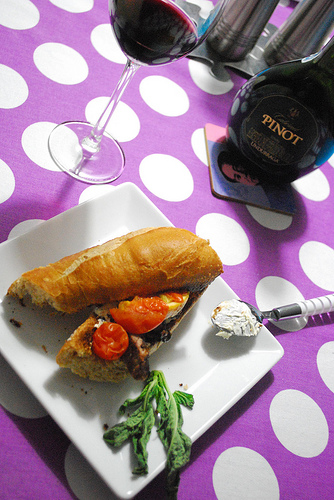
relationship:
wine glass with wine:
[46, 0, 225, 185] [108, 0, 198, 67]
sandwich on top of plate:
[8, 222, 224, 384] [1, 181, 285, 500]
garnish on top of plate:
[104, 367, 195, 476] [1, 181, 285, 500]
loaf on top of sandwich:
[8, 225, 223, 312] [8, 222, 224, 384]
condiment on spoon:
[212, 298, 261, 342] [211, 293, 332, 341]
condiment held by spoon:
[212, 298, 261, 342] [211, 293, 332, 341]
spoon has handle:
[211, 293, 332, 341] [298, 287, 333, 317]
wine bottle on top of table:
[226, 30, 333, 180] [1, 0, 333, 498]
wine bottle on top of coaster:
[226, 30, 333, 180] [202, 120, 295, 215]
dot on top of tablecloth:
[137, 151, 193, 206] [0, 0, 333, 499]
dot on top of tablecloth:
[193, 210, 250, 267] [0, 0, 333, 499]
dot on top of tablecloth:
[31, 40, 91, 86] [0, 0, 333, 499]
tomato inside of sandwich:
[92, 291, 184, 357] [8, 222, 224, 384]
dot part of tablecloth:
[137, 151, 193, 206] [0, 0, 333, 499]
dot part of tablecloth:
[193, 210, 250, 267] [0, 0, 333, 499]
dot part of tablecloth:
[31, 40, 91, 86] [0, 0, 333, 499]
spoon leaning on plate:
[211, 293, 332, 341] [1, 181, 285, 500]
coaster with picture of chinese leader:
[202, 120, 295, 215] [216, 147, 278, 187]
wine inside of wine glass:
[108, 0, 198, 67] [46, 0, 225, 185]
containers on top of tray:
[207, 0, 332, 62] [176, 1, 281, 83]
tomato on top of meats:
[92, 291, 184, 357] [96, 304, 173, 378]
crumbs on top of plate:
[8, 301, 96, 401] [1, 181, 285, 500]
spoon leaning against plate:
[211, 293, 332, 341] [1, 181, 285, 500]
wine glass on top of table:
[46, 0, 225, 185] [1, 0, 333, 498]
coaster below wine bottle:
[202, 120, 295, 215] [226, 30, 333, 180]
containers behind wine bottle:
[207, 0, 332, 62] [226, 30, 333, 180]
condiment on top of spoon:
[212, 298, 261, 342] [211, 293, 332, 341]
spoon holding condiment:
[211, 293, 332, 341] [212, 298, 261, 342]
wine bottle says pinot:
[226, 30, 333, 180] [261, 110, 303, 147]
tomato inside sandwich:
[92, 291, 184, 357] [8, 222, 224, 384]